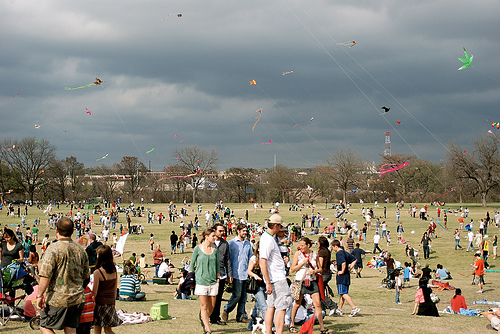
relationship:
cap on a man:
[268, 212, 286, 229] [261, 209, 293, 333]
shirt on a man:
[43, 241, 92, 303] [45, 217, 84, 334]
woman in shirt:
[1, 230, 21, 273] [2, 243, 23, 265]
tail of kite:
[64, 81, 96, 91] [93, 75, 103, 88]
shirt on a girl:
[97, 276, 117, 303] [93, 249, 119, 332]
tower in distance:
[383, 127, 392, 159] [5, 9, 491, 206]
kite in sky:
[453, 47, 478, 74] [4, 4, 499, 157]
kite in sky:
[377, 158, 408, 176] [4, 4, 499, 157]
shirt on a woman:
[193, 243, 220, 285] [197, 230, 220, 330]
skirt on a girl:
[97, 303, 120, 324] [93, 249, 119, 332]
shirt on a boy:
[78, 287, 94, 322] [81, 279, 97, 333]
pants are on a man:
[35, 299, 85, 330] [45, 217, 84, 334]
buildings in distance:
[35, 171, 377, 198] [5, 9, 491, 206]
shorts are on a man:
[335, 283, 351, 295] [331, 239, 356, 317]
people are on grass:
[410, 277, 470, 319] [4, 204, 497, 334]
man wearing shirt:
[261, 209, 293, 333] [262, 234, 286, 280]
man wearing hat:
[261, 209, 293, 333] [268, 212, 286, 229]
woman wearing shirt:
[197, 230, 220, 330] [193, 243, 220, 285]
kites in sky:
[247, 69, 314, 154] [4, 4, 499, 157]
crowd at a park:
[19, 208, 493, 319] [8, 163, 498, 333]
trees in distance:
[5, 166, 499, 201] [5, 9, 491, 206]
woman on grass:
[409, 276, 438, 316] [4, 204, 497, 334]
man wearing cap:
[261, 209, 293, 333] [268, 212, 286, 229]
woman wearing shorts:
[197, 230, 220, 330] [192, 283, 222, 297]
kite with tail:
[185, 166, 204, 179] [154, 171, 194, 182]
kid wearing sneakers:
[394, 270, 402, 304] [396, 300, 402, 304]